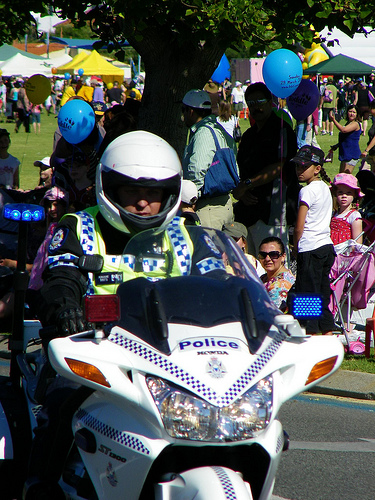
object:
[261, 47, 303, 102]
balloon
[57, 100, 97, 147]
balloon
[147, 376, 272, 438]
front headlight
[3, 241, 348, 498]
motorcycle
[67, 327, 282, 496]
stripe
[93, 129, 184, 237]
helmet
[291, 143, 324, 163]
hat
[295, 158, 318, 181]
head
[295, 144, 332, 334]
girl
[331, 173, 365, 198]
hat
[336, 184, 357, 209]
head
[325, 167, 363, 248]
girl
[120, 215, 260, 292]
windshield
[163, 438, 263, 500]
fender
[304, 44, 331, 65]
balloon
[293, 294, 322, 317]
light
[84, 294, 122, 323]
light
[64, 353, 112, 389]
light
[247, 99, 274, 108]
sunglasses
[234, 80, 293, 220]
man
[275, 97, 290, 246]
string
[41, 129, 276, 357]
police officer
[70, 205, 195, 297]
safety vest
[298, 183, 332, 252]
shirt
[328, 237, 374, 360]
stroller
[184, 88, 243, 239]
person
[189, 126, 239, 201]
bag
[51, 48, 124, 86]
awning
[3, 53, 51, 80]
awning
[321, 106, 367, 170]
woman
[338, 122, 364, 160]
top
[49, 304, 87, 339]
handles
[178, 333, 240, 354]
police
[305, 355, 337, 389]
light